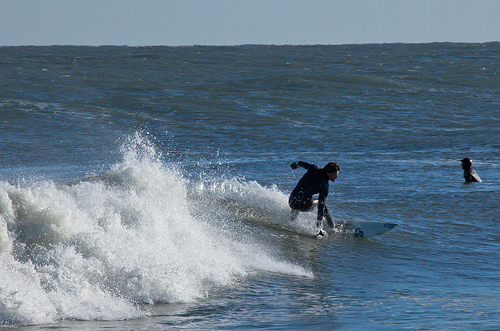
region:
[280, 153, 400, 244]
surfer riding the ocean waves.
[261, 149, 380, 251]
surfer in the water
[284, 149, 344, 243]
surfer in the water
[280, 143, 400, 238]
Surfer on the water.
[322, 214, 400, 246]
Blue surfboard on the water.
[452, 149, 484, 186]
person in the water.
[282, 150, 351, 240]
Wetsuit on the man.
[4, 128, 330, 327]
White waves in the water.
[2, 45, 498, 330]
Blue water covering the surface.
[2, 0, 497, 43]
Blue sky in the background.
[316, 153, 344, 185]
brown hair on the man.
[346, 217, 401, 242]
Dark blue decals on the surfboard.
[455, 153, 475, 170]
hat on the person.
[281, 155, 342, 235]
a man standing on a surfboard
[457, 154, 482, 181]
a man sitting in the water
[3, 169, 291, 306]
the white part of the wave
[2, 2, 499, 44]
the blue sky above everything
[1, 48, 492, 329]
the ocean with mostly calm water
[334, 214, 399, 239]
the surfboard the man is riding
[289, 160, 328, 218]
the wetsuit the man is wearing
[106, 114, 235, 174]
water splashing into the air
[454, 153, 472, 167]
the hat on the man's head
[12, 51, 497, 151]
the calm part of the ocean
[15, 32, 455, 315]
A person is at the beach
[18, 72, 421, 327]
A person is in the water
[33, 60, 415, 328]
A person is getting very wet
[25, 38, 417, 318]
A person is wearing a wetsuit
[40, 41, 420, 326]
A person is on a surfboard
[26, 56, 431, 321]
A person is taking a day off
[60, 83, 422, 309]
A person is on their vacation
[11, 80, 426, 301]
A person is out in the sunshine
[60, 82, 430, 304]
A person is out in the daytime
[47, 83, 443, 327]
A person is enjoying their day